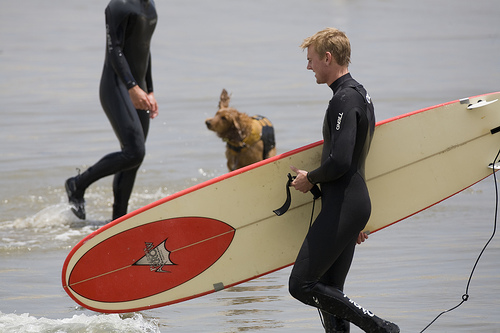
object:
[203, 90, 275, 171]
dog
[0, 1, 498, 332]
water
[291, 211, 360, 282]
thigh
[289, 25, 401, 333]
surfer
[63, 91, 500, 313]
surfboard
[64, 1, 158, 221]
surfer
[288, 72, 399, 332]
wetsuit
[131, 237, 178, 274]
logo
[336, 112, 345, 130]
logo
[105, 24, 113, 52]
logo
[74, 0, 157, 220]
wetsuit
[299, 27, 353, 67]
hair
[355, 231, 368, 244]
hand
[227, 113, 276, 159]
harness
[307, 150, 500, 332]
cord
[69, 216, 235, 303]
spot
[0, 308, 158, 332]
splashes